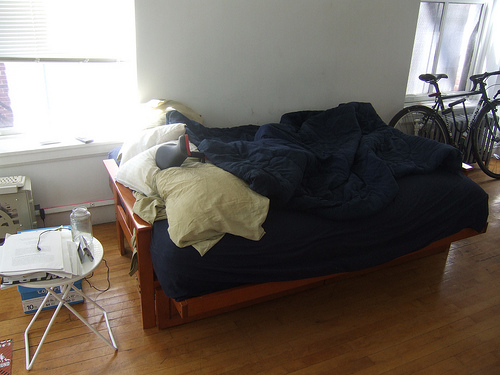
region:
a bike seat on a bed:
[156, 133, 206, 182]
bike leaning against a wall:
[414, 75, 499, 175]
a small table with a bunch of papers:
[24, 212, 116, 362]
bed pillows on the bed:
[140, 138, 255, 265]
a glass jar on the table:
[69, 195, 102, 265]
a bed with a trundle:
[112, 95, 484, 336]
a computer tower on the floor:
[9, 163, 44, 231]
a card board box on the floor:
[22, 282, 94, 307]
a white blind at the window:
[4, 6, 139, 71]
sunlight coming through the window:
[11, 60, 153, 151]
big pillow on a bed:
[157, 161, 262, 259]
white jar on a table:
[60, 200, 98, 252]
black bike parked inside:
[385, 58, 499, 188]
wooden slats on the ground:
[260, 307, 380, 373]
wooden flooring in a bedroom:
[315, 302, 420, 372]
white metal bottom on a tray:
[15, 283, 124, 366]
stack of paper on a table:
[3, 225, 71, 283]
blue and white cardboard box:
[10, 273, 86, 321]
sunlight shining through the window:
[30, 60, 165, 157]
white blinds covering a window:
[5, 11, 118, 78]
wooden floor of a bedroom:
[236, 309, 498, 370]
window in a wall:
[0, 3, 135, 110]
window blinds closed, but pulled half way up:
[1, 1, 130, 63]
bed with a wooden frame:
[105, 158, 166, 319]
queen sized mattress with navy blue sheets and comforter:
[151, 107, 455, 288]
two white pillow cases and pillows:
[133, 128, 267, 240]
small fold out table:
[14, 235, 117, 351]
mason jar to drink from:
[70, 203, 96, 240]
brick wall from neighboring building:
[1, 58, 20, 124]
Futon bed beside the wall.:
[101, 97, 490, 327]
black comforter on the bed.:
[122, 99, 462, 216]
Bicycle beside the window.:
[389, 63, 497, 180]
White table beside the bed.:
[7, 223, 119, 367]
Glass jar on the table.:
[68, 203, 97, 257]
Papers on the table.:
[2, 225, 79, 278]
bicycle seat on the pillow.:
[152, 134, 207, 174]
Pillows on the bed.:
[113, 108, 272, 241]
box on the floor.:
[10, 273, 86, 315]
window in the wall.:
[3, 0, 153, 162]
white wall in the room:
[131, 16, 421, 116]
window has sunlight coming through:
[0, 15, 131, 152]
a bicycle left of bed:
[395, 69, 497, 169]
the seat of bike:
[415, 70, 450, 83]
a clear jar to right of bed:
[70, 206, 97, 243]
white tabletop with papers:
[0, 230, 110, 286]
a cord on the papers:
[34, 221, 61, 253]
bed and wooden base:
[129, 237, 467, 329]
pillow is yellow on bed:
[151, 167, 278, 242]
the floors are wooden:
[281, 309, 481, 371]